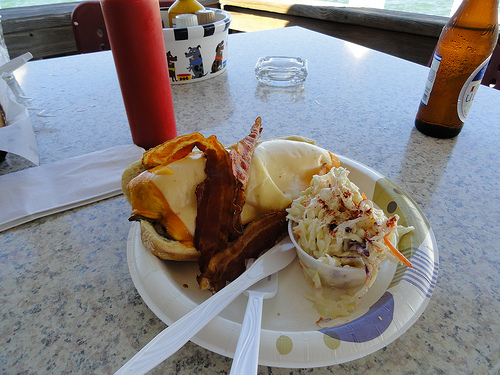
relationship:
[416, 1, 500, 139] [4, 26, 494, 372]
bottle on top of table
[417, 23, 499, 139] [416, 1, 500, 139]
beer inside of bottle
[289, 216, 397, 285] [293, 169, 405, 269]
cup filled with cole slaw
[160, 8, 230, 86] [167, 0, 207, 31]
bowl has mustard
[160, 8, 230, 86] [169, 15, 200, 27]
bowl has salt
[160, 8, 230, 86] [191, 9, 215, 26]
bowl has pepper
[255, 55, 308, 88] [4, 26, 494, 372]
ashtray on top of table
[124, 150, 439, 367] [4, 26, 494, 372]
plate on top of table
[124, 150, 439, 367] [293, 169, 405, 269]
plate has cole slaw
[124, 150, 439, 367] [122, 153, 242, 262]
plate has sandwich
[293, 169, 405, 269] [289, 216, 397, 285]
cole slaw inside of cup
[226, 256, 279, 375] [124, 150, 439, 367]
fork on top of plate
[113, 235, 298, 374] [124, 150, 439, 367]
knife on top of plate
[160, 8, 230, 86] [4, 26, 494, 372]
bowl on top of table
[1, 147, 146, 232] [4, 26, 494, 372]
napkin on top of table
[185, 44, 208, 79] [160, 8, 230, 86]
dog printed on bowl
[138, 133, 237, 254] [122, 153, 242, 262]
bacon on top of sandwich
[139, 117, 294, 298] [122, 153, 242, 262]
bacon on top of sandwich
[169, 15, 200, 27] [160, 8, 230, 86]
salt inside of bowl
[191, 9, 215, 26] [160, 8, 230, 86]
pepper inside of bowl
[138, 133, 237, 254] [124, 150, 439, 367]
bacon on top of plate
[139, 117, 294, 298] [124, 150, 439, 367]
bacon on top of plate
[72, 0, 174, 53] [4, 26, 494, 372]
chair next to table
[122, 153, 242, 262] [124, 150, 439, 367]
sandwich on top of plate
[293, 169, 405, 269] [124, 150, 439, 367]
cole slaw on top of plate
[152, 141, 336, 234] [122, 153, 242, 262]
cheese on top of sandwich